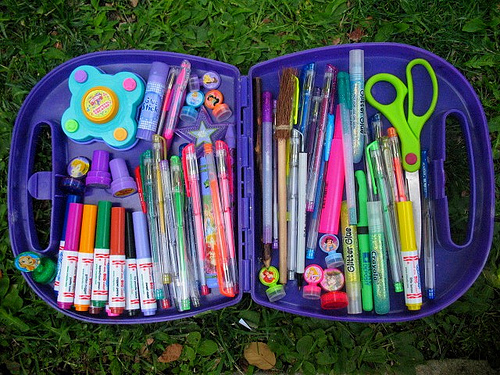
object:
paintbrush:
[298, 61, 318, 150]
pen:
[333, 72, 358, 224]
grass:
[3, 34, 488, 354]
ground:
[23, 31, 495, 365]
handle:
[439, 105, 494, 247]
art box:
[6, 42, 491, 317]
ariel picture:
[260, 269, 276, 284]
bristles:
[274, 65, 297, 140]